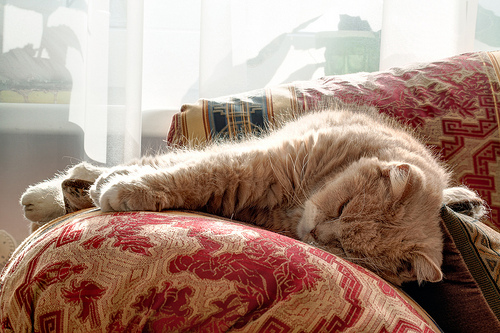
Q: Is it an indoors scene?
A: Yes, it is indoors.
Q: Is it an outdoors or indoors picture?
A: It is indoors.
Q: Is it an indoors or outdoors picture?
A: It is indoors.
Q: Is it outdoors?
A: No, it is indoors.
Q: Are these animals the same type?
A: No, they are cats and seals.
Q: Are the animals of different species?
A: Yes, they are cats and seals.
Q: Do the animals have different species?
A: Yes, they are cats and seals.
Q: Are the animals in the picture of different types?
A: Yes, they are cats and seals.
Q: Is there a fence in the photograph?
A: No, there are no fences.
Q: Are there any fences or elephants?
A: No, there are no fences or elephants.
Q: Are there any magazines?
A: No, there are no magazines.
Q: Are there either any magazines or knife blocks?
A: No, there are no magazines or knife blocks.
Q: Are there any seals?
A: Yes, there is a seal.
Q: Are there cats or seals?
A: Yes, there is a seal.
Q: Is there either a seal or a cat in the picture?
A: Yes, there is a seal.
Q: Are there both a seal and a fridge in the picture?
A: No, there is a seal but no refrigerators.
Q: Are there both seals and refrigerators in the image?
A: No, there is a seal but no refrigerators.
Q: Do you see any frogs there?
A: No, there are no frogs.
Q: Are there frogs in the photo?
A: No, there are no frogs.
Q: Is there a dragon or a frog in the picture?
A: No, there are no frogs or dragons.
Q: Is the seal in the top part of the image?
A: Yes, the seal is in the top of the image.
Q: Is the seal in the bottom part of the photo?
A: No, the seal is in the top of the image.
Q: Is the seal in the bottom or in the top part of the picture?
A: The seal is in the top of the image.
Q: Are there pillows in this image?
A: Yes, there is a pillow.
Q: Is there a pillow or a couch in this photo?
A: Yes, there is a pillow.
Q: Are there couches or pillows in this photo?
A: Yes, there is a pillow.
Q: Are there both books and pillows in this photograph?
A: No, there is a pillow but no books.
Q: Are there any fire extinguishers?
A: No, there are no fire extinguishers.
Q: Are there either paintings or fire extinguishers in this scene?
A: No, there are no fire extinguishers or paintings.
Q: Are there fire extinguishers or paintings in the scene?
A: No, there are no fire extinguishers or paintings.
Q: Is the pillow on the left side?
A: No, the pillow is on the right of the image.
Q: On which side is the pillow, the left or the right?
A: The pillow is on the right of the image.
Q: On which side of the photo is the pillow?
A: The pillow is on the right of the image.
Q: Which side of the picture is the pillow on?
A: The pillow is on the right of the image.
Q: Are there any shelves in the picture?
A: No, there are no shelves.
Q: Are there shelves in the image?
A: No, there are no shelves.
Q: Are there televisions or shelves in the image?
A: No, there are no shelves or televisions.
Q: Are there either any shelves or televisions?
A: No, there are no shelves or televisions.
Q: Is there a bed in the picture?
A: No, there are no beds.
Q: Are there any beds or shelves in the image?
A: No, there are no beds or shelves.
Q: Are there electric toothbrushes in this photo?
A: No, there are no electric toothbrushes.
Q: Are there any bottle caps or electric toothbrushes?
A: No, there are no electric toothbrushes or bottle caps.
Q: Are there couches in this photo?
A: Yes, there is a couch.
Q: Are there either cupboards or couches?
A: Yes, there is a couch.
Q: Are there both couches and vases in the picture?
A: No, there is a couch but no vases.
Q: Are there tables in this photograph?
A: No, there are no tables.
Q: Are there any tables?
A: No, there are no tables.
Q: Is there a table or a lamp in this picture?
A: No, there are no tables or lamps.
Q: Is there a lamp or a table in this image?
A: No, there are no tables or lamps.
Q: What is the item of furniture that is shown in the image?
A: The piece of furniture is a couch.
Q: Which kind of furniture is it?
A: The piece of furniture is a couch.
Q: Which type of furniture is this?
A: This is a couch.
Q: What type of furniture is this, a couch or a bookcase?
A: This is a couch.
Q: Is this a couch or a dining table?
A: This is a couch.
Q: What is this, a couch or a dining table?
A: This is a couch.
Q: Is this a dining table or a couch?
A: This is a couch.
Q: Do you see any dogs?
A: No, there are no dogs.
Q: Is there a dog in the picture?
A: No, there are no dogs.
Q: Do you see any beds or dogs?
A: No, there are no dogs or beds.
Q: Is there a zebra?
A: No, there are no zebras.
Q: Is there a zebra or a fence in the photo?
A: No, there are no zebras or fences.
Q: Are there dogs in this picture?
A: No, there are no dogs.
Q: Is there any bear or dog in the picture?
A: No, there are no dogs or bears.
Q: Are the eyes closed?
A: Yes, the eyes are closed.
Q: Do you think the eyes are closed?
A: Yes, the eyes are closed.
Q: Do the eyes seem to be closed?
A: Yes, the eyes are closed.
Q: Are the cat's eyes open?
A: No, the eyes are closed.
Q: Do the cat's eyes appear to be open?
A: No, the eyes are closed.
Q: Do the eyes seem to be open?
A: No, the eyes are closed.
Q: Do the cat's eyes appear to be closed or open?
A: The eyes are closed.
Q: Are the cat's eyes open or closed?
A: The eyes are closed.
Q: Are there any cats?
A: Yes, there is a cat.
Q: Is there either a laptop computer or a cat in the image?
A: Yes, there is a cat.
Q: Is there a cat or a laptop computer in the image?
A: Yes, there is a cat.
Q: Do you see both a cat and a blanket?
A: No, there is a cat but no blankets.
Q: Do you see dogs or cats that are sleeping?
A: Yes, the cat is sleeping.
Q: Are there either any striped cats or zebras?
A: Yes, there is a striped cat.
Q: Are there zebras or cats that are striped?
A: Yes, the cat is striped.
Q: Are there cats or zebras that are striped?
A: Yes, the cat is striped.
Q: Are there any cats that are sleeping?
A: Yes, there is a cat that is sleeping.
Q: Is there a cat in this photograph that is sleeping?
A: Yes, there is a cat that is sleeping.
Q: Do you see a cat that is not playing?
A: Yes, there is a cat that is sleeping .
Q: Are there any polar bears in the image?
A: No, there are no polar bears.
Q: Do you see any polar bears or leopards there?
A: No, there are no polar bears or leopards.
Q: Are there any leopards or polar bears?
A: No, there are no polar bears or leopards.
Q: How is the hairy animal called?
A: The animal is a cat.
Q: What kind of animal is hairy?
A: The animal is a cat.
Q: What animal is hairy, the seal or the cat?
A: The cat is hairy.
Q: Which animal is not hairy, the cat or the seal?
A: The seal is not hairy.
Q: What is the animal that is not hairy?
A: The animal is a seal.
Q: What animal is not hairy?
A: The animal is a seal.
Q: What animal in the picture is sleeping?
A: The animal is a cat.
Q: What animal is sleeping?
A: The animal is a cat.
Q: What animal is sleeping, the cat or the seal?
A: The cat is sleeping.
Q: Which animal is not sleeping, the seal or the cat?
A: The seal is not sleeping.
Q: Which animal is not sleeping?
A: The animal is a seal.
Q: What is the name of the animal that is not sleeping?
A: The animal is a seal.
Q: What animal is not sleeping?
A: The animal is a seal.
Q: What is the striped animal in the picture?
A: The animal is a cat.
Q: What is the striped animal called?
A: The animal is a cat.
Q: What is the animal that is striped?
A: The animal is a cat.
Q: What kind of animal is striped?
A: The animal is a cat.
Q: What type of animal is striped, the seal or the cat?
A: The cat is striped.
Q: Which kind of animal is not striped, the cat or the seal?
A: The seal is not striped.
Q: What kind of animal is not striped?
A: The animal is a seal.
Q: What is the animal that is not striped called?
A: The animal is a seal.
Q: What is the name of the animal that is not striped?
A: The animal is a seal.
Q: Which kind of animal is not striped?
A: The animal is a seal.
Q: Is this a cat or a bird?
A: This is a cat.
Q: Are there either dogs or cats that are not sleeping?
A: No, there is a cat but it is sleeping.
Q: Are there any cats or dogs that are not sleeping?
A: No, there is a cat but it is sleeping.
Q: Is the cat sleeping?
A: Yes, the cat is sleeping.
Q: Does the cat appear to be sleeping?
A: Yes, the cat is sleeping.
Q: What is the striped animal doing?
A: The cat is sleeping.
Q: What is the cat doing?
A: The cat is sleeping.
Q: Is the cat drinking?
A: No, the cat is sleeping.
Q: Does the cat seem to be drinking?
A: No, the cat is sleeping.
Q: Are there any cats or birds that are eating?
A: No, there is a cat but it is sleeping.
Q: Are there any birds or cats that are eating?
A: No, there is a cat but it is sleeping.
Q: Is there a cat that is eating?
A: No, there is a cat but it is sleeping.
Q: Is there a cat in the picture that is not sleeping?
A: No, there is a cat but it is sleeping.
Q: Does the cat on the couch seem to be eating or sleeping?
A: The cat is sleeping.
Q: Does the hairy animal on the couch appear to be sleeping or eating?
A: The cat is sleeping.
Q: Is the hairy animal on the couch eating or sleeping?
A: The cat is sleeping.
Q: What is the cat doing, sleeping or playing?
A: The cat is sleeping.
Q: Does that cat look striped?
A: Yes, the cat is striped.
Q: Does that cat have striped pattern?
A: Yes, the cat is striped.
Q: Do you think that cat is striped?
A: Yes, the cat is striped.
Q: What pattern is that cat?
A: The cat is striped.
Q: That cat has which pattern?
A: The cat is striped.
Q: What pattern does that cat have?
A: The cat has striped pattern.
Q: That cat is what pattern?
A: The cat is striped.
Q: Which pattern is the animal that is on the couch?
A: The cat is striped.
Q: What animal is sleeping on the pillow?
A: The cat is sleeping on the pillow.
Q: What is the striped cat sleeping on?
A: The cat is sleeping on the pillow.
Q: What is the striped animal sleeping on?
A: The cat is sleeping on the pillow.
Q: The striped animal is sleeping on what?
A: The cat is sleeping on the pillow.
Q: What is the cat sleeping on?
A: The cat is sleeping on the pillow.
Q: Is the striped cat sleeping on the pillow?
A: Yes, the cat is sleeping on the pillow.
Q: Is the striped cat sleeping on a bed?
A: No, the cat is sleeping on the pillow.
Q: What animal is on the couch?
A: The cat is on the couch.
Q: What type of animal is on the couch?
A: The animal is a cat.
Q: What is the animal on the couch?
A: The animal is a cat.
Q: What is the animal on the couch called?
A: The animal is a cat.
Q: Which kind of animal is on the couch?
A: The animal is a cat.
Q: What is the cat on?
A: The cat is on the couch.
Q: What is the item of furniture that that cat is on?
A: The piece of furniture is a couch.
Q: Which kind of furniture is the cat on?
A: The cat is on the couch.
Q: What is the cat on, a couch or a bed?
A: The cat is on a couch.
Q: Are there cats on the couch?
A: Yes, there is a cat on the couch.